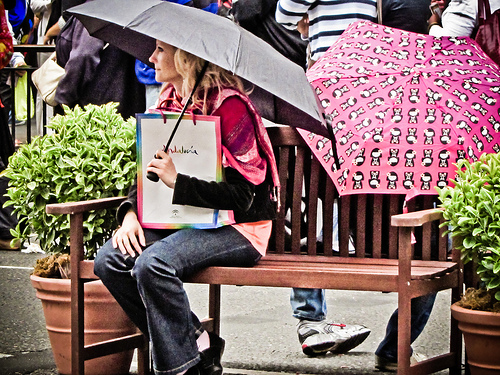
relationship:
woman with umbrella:
[93, 39, 280, 375] [218, 61, 302, 106]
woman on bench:
[90, 37, 284, 372] [41, 119, 480, 372]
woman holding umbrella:
[93, 39, 280, 375] [58, 0, 338, 186]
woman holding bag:
[90, 37, 284, 372] [127, 101, 231, 235]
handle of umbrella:
[141, 67, 207, 187] [58, 0, 338, 186]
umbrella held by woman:
[58, 0, 338, 186] [93, 39, 280, 375]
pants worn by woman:
[81, 207, 269, 373] [93, 39, 280, 375]